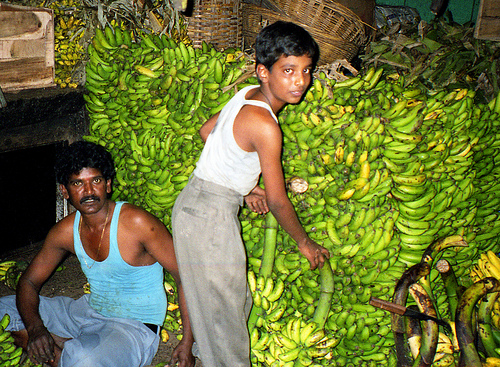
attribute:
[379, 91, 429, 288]
bananas — green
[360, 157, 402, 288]
bananas — green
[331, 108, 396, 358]
bananas — green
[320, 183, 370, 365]
bananas — green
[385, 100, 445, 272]
bananas — green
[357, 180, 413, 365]
bananas — green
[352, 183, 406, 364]
bananas — green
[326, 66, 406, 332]
bananas — green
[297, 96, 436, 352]
bananas — green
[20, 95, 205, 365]
man — sitting down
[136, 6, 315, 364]
body — young, standing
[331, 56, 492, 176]
bananas — bunch, green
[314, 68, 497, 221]
bananas — green, bunch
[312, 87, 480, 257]
bananas — bunch, green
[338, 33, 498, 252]
bananas — green, bunch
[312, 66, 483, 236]
bananas — bunch, green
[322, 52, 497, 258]
bananas — green, bunch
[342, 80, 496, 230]
bananas — bunched, green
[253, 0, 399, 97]
baskets — wicker, stack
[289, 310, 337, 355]
banana — partial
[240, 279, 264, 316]
trouser — partial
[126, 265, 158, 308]
vest — partial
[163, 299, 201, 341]
arm — partial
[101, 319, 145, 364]
jeans — partial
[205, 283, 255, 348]
trouser — partial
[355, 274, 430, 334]
handle — partial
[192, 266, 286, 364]
trouser — partial